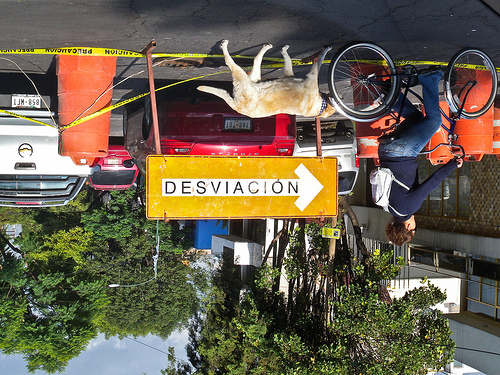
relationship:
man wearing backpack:
[367, 57, 464, 244] [352, 151, 399, 206]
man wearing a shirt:
[367, 57, 464, 244] [378, 155, 460, 220]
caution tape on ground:
[0, 46, 498, 75] [40, 14, 469, 55]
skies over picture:
[93, 346, 146, 368] [2, 6, 498, 373]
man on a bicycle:
[367, 57, 464, 244] [299, 16, 499, 131]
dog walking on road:
[197, 37, 334, 122] [58, 50, 246, 52]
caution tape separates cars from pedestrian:
[0, 42, 498, 130] [336, 42, 473, 246]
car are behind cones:
[0, 93, 93, 208] [13, 53, 161, 93]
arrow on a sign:
[139, 143, 350, 233] [136, 168, 336, 204]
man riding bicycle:
[367, 57, 464, 244] [332, 39, 483, 164]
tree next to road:
[222, 223, 469, 372] [1, 2, 484, 121]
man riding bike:
[367, 57, 464, 244] [270, 29, 494, 138]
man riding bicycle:
[367, 57, 464, 253] [329, 45, 481, 127]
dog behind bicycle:
[197, 37, 334, 122] [329, 42, 498, 165]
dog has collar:
[197, 37, 334, 122] [316, 94, 327, 114]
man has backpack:
[367, 57, 464, 253] [363, 165, 412, 220]